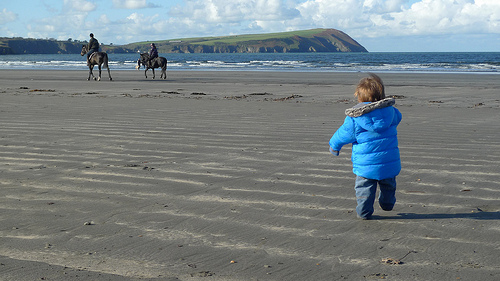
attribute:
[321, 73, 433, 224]
child — white, walking, small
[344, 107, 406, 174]
jacket — blue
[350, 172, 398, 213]
jeans — blue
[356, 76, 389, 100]
hair — short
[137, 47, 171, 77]
horse — black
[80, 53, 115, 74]
horse — black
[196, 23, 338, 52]
hill — green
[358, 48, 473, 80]
water — blue, white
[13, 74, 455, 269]
sand — white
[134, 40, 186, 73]
man — riding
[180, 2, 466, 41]
sky — white